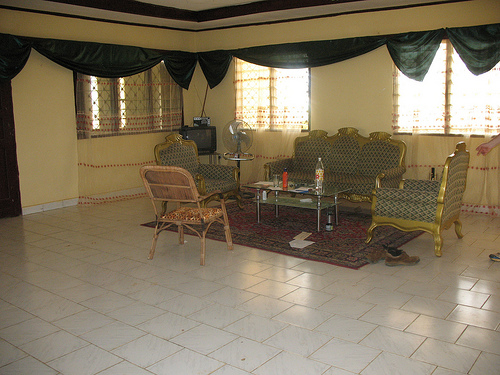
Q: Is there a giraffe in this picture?
A: No, there are no giraffes.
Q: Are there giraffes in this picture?
A: No, there are no giraffes.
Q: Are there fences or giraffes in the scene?
A: No, there are no giraffes or fences.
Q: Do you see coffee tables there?
A: Yes, there is a coffee table.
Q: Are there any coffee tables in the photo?
A: Yes, there is a coffee table.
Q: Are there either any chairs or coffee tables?
A: Yes, there is a coffee table.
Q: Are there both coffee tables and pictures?
A: No, there is a coffee table but no pictures.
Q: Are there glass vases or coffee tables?
A: Yes, there is a glass coffee table.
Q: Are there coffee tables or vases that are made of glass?
A: Yes, the coffee table is made of glass.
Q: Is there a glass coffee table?
A: Yes, there is a coffee table that is made of glass.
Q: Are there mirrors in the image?
A: No, there are no mirrors.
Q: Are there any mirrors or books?
A: No, there are no mirrors or books.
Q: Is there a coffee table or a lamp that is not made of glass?
A: No, there is a coffee table but it is made of glass.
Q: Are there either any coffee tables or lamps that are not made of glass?
A: No, there is a coffee table but it is made of glass.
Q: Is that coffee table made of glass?
A: Yes, the coffee table is made of glass.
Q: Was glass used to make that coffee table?
A: Yes, the coffee table is made of glass.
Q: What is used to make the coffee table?
A: The coffee table is made of glass.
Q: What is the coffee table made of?
A: The coffee table is made of glass.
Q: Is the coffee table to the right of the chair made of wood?
A: No, the coffee table is made of glass.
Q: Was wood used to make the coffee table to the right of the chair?
A: No, the coffee table is made of glass.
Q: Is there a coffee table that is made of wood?
A: No, there is a coffee table but it is made of glass.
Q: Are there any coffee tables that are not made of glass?
A: No, there is a coffee table but it is made of glass.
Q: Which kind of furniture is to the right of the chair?
A: The piece of furniture is a coffee table.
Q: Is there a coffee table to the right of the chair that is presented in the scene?
A: Yes, there is a coffee table to the right of the chair.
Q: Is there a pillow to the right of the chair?
A: No, there is a coffee table to the right of the chair.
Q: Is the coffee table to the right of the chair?
A: Yes, the coffee table is to the right of the chair.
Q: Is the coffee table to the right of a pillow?
A: No, the coffee table is to the right of the chair.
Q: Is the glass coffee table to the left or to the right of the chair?
A: The coffee table is to the right of the chair.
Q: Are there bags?
A: No, there are no bags.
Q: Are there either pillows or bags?
A: No, there are no bags or pillows.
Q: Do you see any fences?
A: No, there are no fences.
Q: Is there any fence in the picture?
A: No, there are no fences.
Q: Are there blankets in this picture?
A: No, there are no blankets.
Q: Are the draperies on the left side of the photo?
A: Yes, the draperies are on the left of the image.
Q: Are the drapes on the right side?
A: No, the drapes are on the left of the image.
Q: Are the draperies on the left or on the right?
A: The draperies are on the left of the image.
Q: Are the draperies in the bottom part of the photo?
A: No, the draperies are in the top of the image.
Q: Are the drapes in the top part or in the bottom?
A: The drapes are in the top of the image.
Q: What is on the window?
A: The drapes are on the window.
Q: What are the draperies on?
A: The draperies are on the window.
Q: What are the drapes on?
A: The draperies are on the window.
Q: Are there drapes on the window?
A: Yes, there are drapes on the window.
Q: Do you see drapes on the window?
A: Yes, there are drapes on the window.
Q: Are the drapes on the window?
A: Yes, the drapes are on the window.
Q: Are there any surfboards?
A: No, there are no surfboards.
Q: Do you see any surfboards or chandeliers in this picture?
A: No, there are no surfboards or chandeliers.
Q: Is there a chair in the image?
A: Yes, there is a chair.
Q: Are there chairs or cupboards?
A: Yes, there is a chair.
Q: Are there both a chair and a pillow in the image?
A: No, there is a chair but no pillows.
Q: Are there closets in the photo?
A: No, there are no closets.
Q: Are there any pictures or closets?
A: No, there are no closets or pictures.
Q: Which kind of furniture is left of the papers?
A: The piece of furniture is a chair.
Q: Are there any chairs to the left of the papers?
A: Yes, there is a chair to the left of the papers.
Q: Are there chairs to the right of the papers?
A: No, the chair is to the left of the papers.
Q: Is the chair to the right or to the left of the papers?
A: The chair is to the left of the papers.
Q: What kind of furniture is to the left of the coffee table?
A: The piece of furniture is a chair.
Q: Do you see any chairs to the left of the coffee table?
A: Yes, there is a chair to the left of the coffee table.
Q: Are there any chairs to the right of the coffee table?
A: No, the chair is to the left of the coffee table.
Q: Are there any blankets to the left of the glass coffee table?
A: No, there is a chair to the left of the coffee table.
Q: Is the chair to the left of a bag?
A: No, the chair is to the left of the coffee table.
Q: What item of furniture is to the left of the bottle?
A: The piece of furniture is a chair.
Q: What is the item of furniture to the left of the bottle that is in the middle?
A: The piece of furniture is a chair.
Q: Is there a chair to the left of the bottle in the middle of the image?
A: Yes, there is a chair to the left of the bottle.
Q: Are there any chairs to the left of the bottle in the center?
A: Yes, there is a chair to the left of the bottle.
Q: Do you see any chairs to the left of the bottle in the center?
A: Yes, there is a chair to the left of the bottle.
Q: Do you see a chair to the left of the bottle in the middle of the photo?
A: Yes, there is a chair to the left of the bottle.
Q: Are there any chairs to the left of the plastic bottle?
A: Yes, there is a chair to the left of the bottle.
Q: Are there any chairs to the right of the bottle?
A: No, the chair is to the left of the bottle.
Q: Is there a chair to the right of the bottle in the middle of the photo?
A: No, the chair is to the left of the bottle.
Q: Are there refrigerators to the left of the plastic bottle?
A: No, there is a chair to the left of the bottle.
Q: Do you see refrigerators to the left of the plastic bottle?
A: No, there is a chair to the left of the bottle.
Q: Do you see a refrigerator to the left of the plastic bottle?
A: No, there is a chair to the left of the bottle.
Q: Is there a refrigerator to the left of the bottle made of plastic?
A: No, there is a chair to the left of the bottle.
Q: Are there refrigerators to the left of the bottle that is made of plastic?
A: No, there is a chair to the left of the bottle.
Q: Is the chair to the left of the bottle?
A: Yes, the chair is to the left of the bottle.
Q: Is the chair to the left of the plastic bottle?
A: Yes, the chair is to the left of the bottle.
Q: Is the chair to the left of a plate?
A: No, the chair is to the left of the bottle.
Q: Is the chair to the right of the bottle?
A: No, the chair is to the left of the bottle.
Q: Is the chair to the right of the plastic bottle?
A: No, the chair is to the left of the bottle.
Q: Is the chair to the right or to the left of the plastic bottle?
A: The chair is to the left of the bottle.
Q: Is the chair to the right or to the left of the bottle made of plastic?
A: The chair is to the left of the bottle.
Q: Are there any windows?
A: Yes, there is a window.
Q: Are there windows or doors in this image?
A: Yes, there is a window.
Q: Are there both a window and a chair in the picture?
A: Yes, there are both a window and a chair.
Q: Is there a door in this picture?
A: No, there are no doors.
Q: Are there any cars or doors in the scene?
A: No, there are no doors or cars.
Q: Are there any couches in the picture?
A: Yes, there is a couch.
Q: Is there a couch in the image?
A: Yes, there is a couch.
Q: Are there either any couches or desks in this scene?
A: Yes, there is a couch.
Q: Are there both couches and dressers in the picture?
A: No, there is a couch but no dressers.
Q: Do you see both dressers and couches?
A: No, there is a couch but no dressers.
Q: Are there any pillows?
A: No, there are no pillows.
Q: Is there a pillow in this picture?
A: No, there are no pillows.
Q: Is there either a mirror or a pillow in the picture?
A: No, there are no pillows or mirrors.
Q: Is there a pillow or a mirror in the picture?
A: No, there are no pillows or mirrors.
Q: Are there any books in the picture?
A: No, there are no books.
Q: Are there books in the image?
A: No, there are no books.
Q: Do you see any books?
A: No, there are no books.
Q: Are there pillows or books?
A: No, there are no books or pillows.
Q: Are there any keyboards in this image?
A: No, there are no keyboards.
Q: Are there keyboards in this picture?
A: No, there are no keyboards.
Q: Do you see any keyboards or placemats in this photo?
A: No, there are no keyboards or placemats.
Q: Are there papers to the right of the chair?
A: Yes, there are papers to the right of the chair.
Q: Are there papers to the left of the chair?
A: No, the papers are to the right of the chair.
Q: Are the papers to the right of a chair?
A: Yes, the papers are to the right of a chair.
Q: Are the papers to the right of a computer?
A: No, the papers are to the right of a chair.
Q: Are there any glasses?
A: No, there are no glasses.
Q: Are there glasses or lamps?
A: No, there are no glasses or lamps.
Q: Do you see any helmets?
A: No, there are no helmets.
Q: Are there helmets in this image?
A: No, there are no helmets.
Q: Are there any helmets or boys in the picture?
A: No, there are no helmets or boys.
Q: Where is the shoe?
A: The shoe is on the floor.